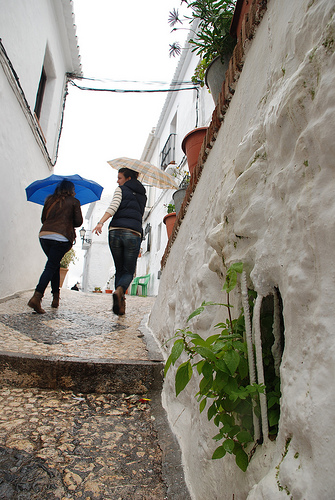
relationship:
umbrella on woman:
[26, 173, 102, 204] [27, 177, 84, 312]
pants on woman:
[108, 228, 140, 291] [90, 166, 147, 314]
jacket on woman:
[37, 190, 85, 242] [27, 177, 84, 312]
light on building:
[80, 224, 90, 241] [78, 182, 135, 293]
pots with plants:
[198, 53, 235, 105] [122, 0, 266, 99]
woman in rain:
[27, 177, 84, 312] [2, 7, 333, 497]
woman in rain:
[90, 166, 147, 314] [2, 7, 333, 497]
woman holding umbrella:
[112, 169, 149, 220] [134, 160, 167, 186]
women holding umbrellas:
[29, 178, 83, 313] [25, 173, 102, 201]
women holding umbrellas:
[92, 167, 139, 314] [108, 156, 180, 190]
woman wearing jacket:
[86, 155, 175, 280] [105, 172, 157, 230]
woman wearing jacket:
[27, 177, 84, 312] [41, 193, 82, 240]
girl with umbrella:
[115, 170, 146, 314] [26, 173, 102, 204]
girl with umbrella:
[37, 184, 87, 270] [110, 156, 178, 187]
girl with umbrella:
[37, 184, 87, 270] [22, 166, 107, 205]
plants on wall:
[178, 277, 256, 423] [138, 58, 333, 500]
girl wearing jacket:
[41, 181, 85, 258] [32, 189, 93, 226]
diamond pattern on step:
[0, 299, 132, 349] [3, 345, 170, 395]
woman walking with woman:
[90, 166, 147, 314] [27, 177, 84, 312]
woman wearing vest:
[90, 166, 147, 314] [109, 178, 147, 233]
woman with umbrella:
[27, 177, 84, 312] [22, 166, 109, 214]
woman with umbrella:
[90, 166, 147, 314] [89, 153, 181, 202]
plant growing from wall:
[167, 239, 285, 455] [135, 1, 332, 498]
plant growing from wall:
[174, 1, 240, 104] [135, 1, 332, 498]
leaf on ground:
[136, 395, 152, 403] [1, 384, 170, 498]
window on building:
[32, 37, 58, 133] [0, 12, 124, 242]